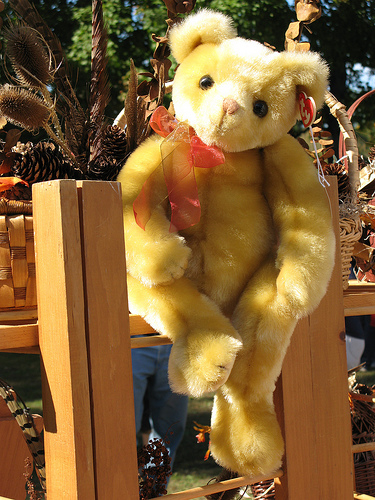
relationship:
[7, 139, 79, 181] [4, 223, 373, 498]
pine cone on a fence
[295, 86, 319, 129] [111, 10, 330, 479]
tag on bear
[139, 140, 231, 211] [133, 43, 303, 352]
bow around bear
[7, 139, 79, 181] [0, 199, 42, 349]
pine cone in basket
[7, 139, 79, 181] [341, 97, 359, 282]
pine cone in basket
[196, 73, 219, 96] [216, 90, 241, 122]
eye and nose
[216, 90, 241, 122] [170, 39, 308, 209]
nose of a teddy bear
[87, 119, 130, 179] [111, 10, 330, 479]
pine cone beside bear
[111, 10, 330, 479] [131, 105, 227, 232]
bear wearing bow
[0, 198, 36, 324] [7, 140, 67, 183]
basket filled with pine cones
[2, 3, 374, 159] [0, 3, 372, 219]
trees are in background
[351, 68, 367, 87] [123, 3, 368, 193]
sky seeing tree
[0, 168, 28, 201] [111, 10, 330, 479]
flowers are near bear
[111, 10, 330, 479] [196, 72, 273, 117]
bear has eyes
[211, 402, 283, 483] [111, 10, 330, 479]
foot has bear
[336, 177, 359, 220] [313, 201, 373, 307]
moss in basket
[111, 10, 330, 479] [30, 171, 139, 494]
bear sitting on ladder